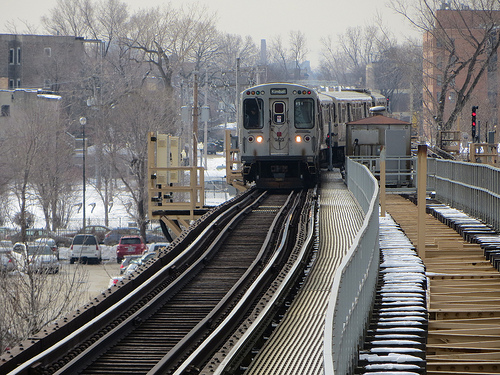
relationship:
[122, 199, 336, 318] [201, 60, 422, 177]
tracks for train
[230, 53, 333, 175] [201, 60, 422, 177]
front of train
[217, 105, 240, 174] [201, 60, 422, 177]
spoke next to train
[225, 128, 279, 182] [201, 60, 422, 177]
light on train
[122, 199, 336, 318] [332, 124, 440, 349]
tracks beside fence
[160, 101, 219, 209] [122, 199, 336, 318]
post near tracks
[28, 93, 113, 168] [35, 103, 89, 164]
trees with leaves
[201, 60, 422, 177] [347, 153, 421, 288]
train beside platform